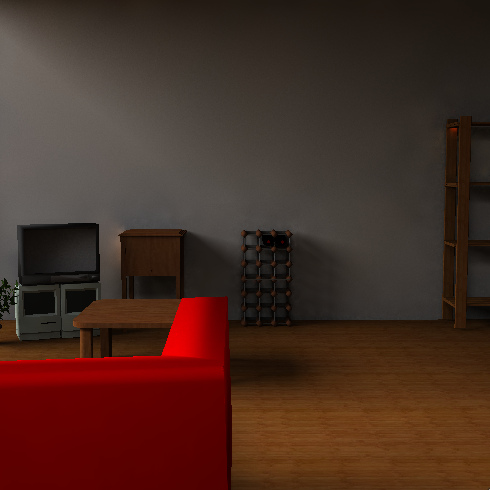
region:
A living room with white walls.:
[0, 0, 489, 489]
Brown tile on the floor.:
[0, 319, 488, 489]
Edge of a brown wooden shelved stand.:
[438, 110, 487, 327]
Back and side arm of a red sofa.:
[0, 295, 228, 489]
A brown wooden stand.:
[118, 226, 183, 298]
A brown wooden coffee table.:
[72, 297, 180, 356]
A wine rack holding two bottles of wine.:
[236, 227, 292, 330]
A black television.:
[17, 220, 100, 285]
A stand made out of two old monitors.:
[11, 278, 102, 339]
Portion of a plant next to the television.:
[0, 276, 20, 316]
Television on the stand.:
[14, 224, 105, 296]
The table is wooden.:
[65, 280, 195, 350]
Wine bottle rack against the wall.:
[248, 220, 301, 344]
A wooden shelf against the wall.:
[421, 108, 487, 330]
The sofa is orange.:
[44, 331, 247, 466]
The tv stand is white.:
[12, 289, 108, 342]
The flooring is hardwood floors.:
[255, 327, 443, 450]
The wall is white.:
[90, 71, 390, 208]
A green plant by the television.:
[1, 277, 26, 335]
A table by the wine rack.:
[99, 212, 202, 314]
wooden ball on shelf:
[239, 229, 247, 238]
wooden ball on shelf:
[253, 228, 262, 237]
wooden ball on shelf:
[267, 228, 278, 239]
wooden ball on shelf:
[283, 227, 292, 237]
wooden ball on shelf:
[251, 243, 265, 253]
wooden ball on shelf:
[267, 245, 278, 256]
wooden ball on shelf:
[283, 244, 292, 254]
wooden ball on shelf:
[237, 314, 248, 328]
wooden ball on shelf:
[253, 301, 264, 312]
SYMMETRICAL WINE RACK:
[236, 229, 298, 329]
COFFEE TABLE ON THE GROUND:
[71, 295, 178, 358]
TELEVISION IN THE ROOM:
[17, 222, 99, 283]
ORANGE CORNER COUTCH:
[3, 296, 235, 481]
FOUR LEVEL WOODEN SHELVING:
[444, 112, 486, 324]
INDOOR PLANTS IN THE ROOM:
[0, 275, 15, 318]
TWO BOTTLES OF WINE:
[259, 228, 288, 250]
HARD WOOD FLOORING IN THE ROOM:
[228, 319, 487, 481]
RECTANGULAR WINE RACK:
[238, 227, 297, 327]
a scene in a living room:
[6, 3, 487, 488]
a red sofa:
[0, 286, 249, 489]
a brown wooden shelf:
[422, 84, 489, 348]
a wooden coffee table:
[66, 275, 224, 392]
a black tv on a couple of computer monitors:
[11, 209, 114, 360]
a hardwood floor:
[4, 306, 485, 482]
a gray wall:
[3, 6, 488, 347]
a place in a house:
[4, 6, 477, 487]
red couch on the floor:
[29, 347, 240, 435]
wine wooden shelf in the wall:
[238, 229, 296, 317]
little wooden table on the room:
[85, 303, 165, 331]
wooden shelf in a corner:
[458, 127, 474, 311]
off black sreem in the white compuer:
[19, 294, 53, 319]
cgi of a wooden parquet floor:
[283, 441, 327, 487]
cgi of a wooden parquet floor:
[323, 439, 379, 487]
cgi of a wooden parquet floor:
[375, 437, 428, 488]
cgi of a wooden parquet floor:
[424, 434, 489, 485]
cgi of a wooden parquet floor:
[421, 385, 486, 441]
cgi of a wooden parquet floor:
[359, 380, 419, 433]